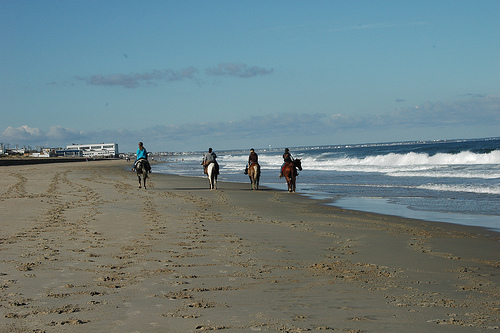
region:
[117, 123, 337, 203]
The horses are together.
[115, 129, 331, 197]
Four people ride horses along the beach.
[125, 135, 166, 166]
The rider wears a blue jacket.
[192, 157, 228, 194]
The horse is white.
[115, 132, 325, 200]
The horses face away from the camera.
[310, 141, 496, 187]
The waves are crashing on the shore.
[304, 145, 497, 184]
The waves are white.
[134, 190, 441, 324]
The horse leave hoof prints in the sand.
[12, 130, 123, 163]
A building is on the beach.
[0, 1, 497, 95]
The sky is blue.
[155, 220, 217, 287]
footprints in the sand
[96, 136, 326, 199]
horses on the beach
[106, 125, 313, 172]
riders on the horses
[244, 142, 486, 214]
surf on the beach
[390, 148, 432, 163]
water spray in air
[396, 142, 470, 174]
waves crashing on beach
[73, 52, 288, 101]
clouds in blue sky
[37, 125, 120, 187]
building on the beach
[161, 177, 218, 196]
shadow of the rider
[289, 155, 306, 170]
horse head facing water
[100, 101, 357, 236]
people on horseback on the beach.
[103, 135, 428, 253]
People on the beach.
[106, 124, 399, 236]
Horses with people on them.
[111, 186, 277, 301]
Footprints in the sand.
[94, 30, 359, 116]
Clouds in the sky,.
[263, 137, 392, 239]
Water by the beach.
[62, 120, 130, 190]
Buildings on the beach.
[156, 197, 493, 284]
Sand on the shore.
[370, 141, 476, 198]
Waves in the water.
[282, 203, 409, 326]
Clumps of sand.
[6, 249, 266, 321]
The sand is wet.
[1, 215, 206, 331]
The sand is tan.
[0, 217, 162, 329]
Tracks are in the sand.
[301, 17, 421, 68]
The sky is blue.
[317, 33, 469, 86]
The sky is clear.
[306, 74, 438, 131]
A few clouds are in the sky.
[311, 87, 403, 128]
The clouds are gray and white.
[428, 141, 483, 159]
The water is blue.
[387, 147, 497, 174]
The waves are white.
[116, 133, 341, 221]
Four people are riding horses.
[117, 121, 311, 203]
the horses on the beach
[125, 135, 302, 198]
the horses walking on the beach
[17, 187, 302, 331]
the footprints in the sand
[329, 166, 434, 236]
the wet sand near the water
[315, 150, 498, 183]
the white waves breaking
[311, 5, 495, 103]
the clear blue sky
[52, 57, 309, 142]
the clouds in the sky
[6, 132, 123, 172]
the buildings in the distance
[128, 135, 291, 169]
the people riding on the horses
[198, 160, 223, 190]
the white horse